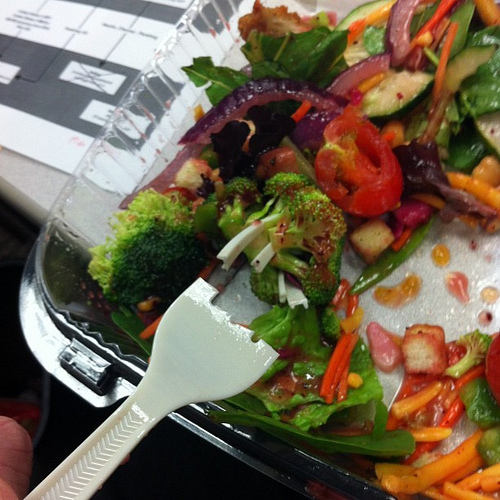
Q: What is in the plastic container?
A: Vegetables.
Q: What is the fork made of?
A: Plastic.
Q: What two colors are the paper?
A: White and grey.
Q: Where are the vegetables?
A: A plastic container.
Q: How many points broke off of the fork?
A: 4.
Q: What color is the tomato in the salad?
A: Red.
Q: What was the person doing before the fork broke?
A: Eating.